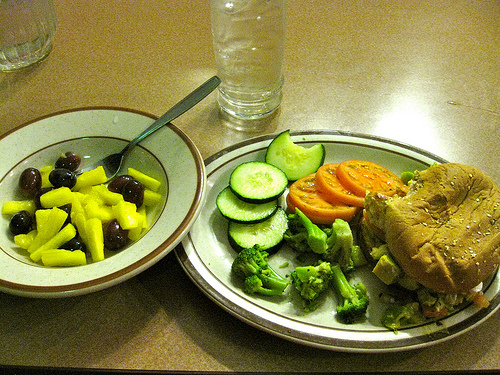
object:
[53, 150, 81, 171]
meal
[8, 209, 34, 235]
fruit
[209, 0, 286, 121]
water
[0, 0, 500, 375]
table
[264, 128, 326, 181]
cucummber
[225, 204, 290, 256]
slices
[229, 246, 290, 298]
broccoli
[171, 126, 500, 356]
plate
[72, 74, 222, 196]
spoon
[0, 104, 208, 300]
bowl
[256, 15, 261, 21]
ice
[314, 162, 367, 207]
tomatoes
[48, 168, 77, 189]
grape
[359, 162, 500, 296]
hamburger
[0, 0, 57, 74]
jug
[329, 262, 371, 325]
vegetables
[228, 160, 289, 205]
cucumber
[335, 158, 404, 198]
tomatoe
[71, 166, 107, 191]
pineapple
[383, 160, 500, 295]
bun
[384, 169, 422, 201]
bite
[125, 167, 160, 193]
pineapples